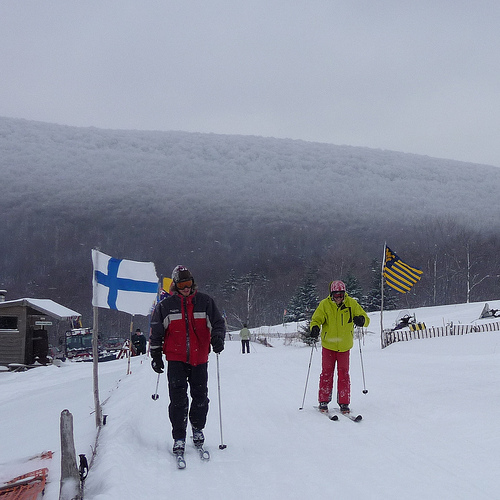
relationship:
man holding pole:
[310, 280, 370, 413] [356, 323, 370, 398]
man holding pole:
[310, 280, 370, 413] [292, 341, 317, 413]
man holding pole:
[148, 265, 226, 454] [146, 365, 162, 401]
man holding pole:
[148, 265, 226, 454] [212, 352, 230, 452]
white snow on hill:
[3, 116, 499, 497] [3, 301, 499, 499]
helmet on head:
[327, 277, 347, 306] [326, 278, 349, 307]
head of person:
[326, 278, 349, 307] [298, 279, 370, 409]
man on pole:
[310, 280, 370, 413] [152, 373, 160, 401]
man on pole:
[148, 265, 226, 454] [152, 373, 160, 401]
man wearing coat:
[310, 280, 370, 413] [310, 291, 370, 352]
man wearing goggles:
[148, 265, 226, 454] [175, 279, 192, 290]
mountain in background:
[4, 100, 499, 277] [1, 62, 498, 337]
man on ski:
[144, 258, 226, 470] [192, 427, 212, 465]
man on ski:
[306, 273, 373, 428] [318, 401, 339, 430]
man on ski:
[306, 273, 373, 428] [341, 401, 364, 426]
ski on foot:
[310, 398, 340, 423] [315, 395, 331, 415]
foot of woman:
[315, 395, 331, 415] [299, 276, 370, 409]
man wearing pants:
[310, 280, 370, 413] [319, 351, 351, 404]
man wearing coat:
[148, 265, 226, 454] [131, 261, 256, 475]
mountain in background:
[4, 100, 499, 343] [3, 38, 499, 391]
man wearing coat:
[310, 280, 370, 413] [304, 291, 374, 356]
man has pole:
[148, 265, 226, 454] [216, 354, 227, 450]